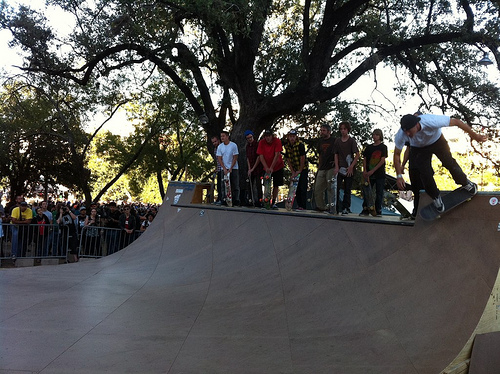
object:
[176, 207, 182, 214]
spotted-white mark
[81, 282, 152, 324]
line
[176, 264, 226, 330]
line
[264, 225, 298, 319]
line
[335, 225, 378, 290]
line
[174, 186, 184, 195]
sticker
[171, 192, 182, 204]
sticker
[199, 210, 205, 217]
sticker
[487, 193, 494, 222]
mark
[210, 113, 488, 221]
skateboarders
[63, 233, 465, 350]
ramp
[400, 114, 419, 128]
hat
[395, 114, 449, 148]
shirt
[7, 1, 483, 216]
tree